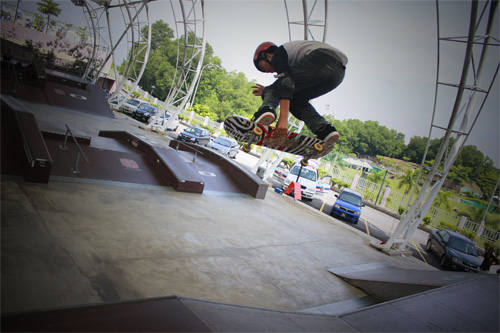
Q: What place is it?
A: It is a parking lot.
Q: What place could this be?
A: It is a parking lot.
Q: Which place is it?
A: It is a parking lot.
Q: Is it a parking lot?
A: Yes, it is a parking lot.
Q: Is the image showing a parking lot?
A: Yes, it is showing a parking lot.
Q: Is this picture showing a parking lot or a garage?
A: It is showing a parking lot.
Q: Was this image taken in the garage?
A: No, the picture was taken in the parking lot.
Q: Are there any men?
A: No, there are no men.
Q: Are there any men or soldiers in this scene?
A: No, there are no men or soldiers.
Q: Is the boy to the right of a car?
A: Yes, the boy is to the right of a car.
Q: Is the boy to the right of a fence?
A: No, the boy is to the right of a car.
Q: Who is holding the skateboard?
A: The boy is holding the skateboard.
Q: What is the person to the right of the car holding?
A: The boy is holding the skateboard.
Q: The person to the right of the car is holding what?
A: The boy is holding the skateboard.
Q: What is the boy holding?
A: The boy is holding the skateboard.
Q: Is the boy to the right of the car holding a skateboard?
A: Yes, the boy is holding a skateboard.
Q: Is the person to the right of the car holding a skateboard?
A: Yes, the boy is holding a skateboard.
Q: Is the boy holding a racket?
A: No, the boy is holding a skateboard.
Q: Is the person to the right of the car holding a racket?
A: No, the boy is holding a skateboard.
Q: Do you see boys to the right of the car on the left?
A: Yes, there is a boy to the right of the car.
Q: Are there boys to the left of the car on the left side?
A: No, the boy is to the right of the car.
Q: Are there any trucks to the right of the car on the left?
A: No, there is a boy to the right of the car.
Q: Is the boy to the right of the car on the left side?
A: Yes, the boy is to the right of the car.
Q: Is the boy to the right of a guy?
A: No, the boy is to the right of the car.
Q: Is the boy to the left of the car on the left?
A: No, the boy is to the right of the car.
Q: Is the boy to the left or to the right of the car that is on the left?
A: The boy is to the right of the car.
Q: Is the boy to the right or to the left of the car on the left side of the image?
A: The boy is to the right of the car.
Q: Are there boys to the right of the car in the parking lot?
A: Yes, there is a boy to the right of the car.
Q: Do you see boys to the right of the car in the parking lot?
A: Yes, there is a boy to the right of the car.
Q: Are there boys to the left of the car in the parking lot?
A: No, the boy is to the right of the car.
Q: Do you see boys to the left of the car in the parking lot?
A: No, the boy is to the right of the car.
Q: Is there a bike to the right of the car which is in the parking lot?
A: No, there is a boy to the right of the car.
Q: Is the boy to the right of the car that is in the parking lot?
A: Yes, the boy is to the right of the car.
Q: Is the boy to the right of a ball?
A: No, the boy is to the right of the car.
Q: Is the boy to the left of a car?
A: No, the boy is to the right of a car.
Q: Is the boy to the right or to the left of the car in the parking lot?
A: The boy is to the right of the car.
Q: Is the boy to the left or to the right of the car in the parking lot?
A: The boy is to the right of the car.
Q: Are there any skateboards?
A: Yes, there is a skateboard.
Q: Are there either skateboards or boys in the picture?
A: Yes, there is a skateboard.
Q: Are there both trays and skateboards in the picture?
A: No, there is a skateboard but no trays.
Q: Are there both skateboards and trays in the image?
A: No, there is a skateboard but no trays.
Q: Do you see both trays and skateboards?
A: No, there is a skateboard but no trays.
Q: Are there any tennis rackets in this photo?
A: No, there are no tennis rackets.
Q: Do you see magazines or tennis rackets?
A: No, there are no tennis rackets or magazines.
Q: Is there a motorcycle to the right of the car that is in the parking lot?
A: No, there is a skateboard to the right of the car.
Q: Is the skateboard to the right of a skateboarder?
A: No, the skateboard is to the right of the car.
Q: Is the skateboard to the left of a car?
A: No, the skateboard is to the right of a car.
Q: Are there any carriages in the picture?
A: No, there are no carriages.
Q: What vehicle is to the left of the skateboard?
A: The vehicle is a car.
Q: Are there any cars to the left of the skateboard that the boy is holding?
A: Yes, there is a car to the left of the skateboard.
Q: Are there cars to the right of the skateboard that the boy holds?
A: No, the car is to the left of the skateboard.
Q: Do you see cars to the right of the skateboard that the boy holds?
A: No, the car is to the left of the skateboard.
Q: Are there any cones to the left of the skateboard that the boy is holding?
A: No, there is a car to the left of the skateboard.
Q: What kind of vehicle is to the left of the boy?
A: The vehicle is a car.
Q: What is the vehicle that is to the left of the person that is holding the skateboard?
A: The vehicle is a car.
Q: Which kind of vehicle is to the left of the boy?
A: The vehicle is a car.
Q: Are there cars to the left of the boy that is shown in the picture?
A: Yes, there is a car to the left of the boy.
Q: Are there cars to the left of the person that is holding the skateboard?
A: Yes, there is a car to the left of the boy.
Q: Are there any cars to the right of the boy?
A: No, the car is to the left of the boy.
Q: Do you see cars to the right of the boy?
A: No, the car is to the left of the boy.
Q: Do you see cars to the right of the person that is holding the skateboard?
A: No, the car is to the left of the boy.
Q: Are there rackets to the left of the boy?
A: No, there is a car to the left of the boy.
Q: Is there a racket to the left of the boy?
A: No, there is a car to the left of the boy.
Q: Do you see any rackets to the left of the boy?
A: No, there is a car to the left of the boy.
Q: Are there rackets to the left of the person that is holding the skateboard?
A: No, there is a car to the left of the boy.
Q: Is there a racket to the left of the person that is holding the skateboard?
A: No, there is a car to the left of the boy.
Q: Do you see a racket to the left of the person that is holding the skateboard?
A: No, there is a car to the left of the boy.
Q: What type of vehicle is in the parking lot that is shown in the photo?
A: The vehicle is a car.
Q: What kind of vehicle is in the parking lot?
A: The vehicle is a car.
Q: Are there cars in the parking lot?
A: Yes, there is a car in the parking lot.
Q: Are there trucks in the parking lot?
A: No, there is a car in the parking lot.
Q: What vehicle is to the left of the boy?
A: The vehicle is a car.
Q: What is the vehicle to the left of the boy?
A: The vehicle is a car.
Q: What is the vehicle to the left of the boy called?
A: The vehicle is a car.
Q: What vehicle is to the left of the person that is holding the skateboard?
A: The vehicle is a car.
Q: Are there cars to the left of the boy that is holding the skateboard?
A: Yes, there is a car to the left of the boy.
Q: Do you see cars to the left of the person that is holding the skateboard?
A: Yes, there is a car to the left of the boy.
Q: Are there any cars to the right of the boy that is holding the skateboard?
A: No, the car is to the left of the boy.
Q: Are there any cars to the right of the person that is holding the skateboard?
A: No, the car is to the left of the boy.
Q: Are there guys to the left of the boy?
A: No, there is a car to the left of the boy.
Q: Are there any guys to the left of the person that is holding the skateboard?
A: No, there is a car to the left of the boy.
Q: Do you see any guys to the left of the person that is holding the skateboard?
A: No, there is a car to the left of the boy.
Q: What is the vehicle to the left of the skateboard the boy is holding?
A: The vehicle is a car.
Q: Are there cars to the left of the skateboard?
A: Yes, there is a car to the left of the skateboard.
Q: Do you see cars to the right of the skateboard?
A: No, the car is to the left of the skateboard.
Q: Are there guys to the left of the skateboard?
A: No, there is a car to the left of the skateboard.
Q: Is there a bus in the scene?
A: No, there are no buses.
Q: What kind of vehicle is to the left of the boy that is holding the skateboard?
A: The vehicle is a car.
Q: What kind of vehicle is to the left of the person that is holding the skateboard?
A: The vehicle is a car.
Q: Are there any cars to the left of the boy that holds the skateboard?
A: Yes, there is a car to the left of the boy.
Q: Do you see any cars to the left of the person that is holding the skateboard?
A: Yes, there is a car to the left of the boy.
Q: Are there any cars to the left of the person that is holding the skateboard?
A: Yes, there is a car to the left of the boy.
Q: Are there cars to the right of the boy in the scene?
A: No, the car is to the left of the boy.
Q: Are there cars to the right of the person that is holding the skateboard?
A: No, the car is to the left of the boy.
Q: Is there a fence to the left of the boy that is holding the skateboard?
A: No, there is a car to the left of the boy.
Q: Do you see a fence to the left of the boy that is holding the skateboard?
A: No, there is a car to the left of the boy.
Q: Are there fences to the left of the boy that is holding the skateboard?
A: No, there is a car to the left of the boy.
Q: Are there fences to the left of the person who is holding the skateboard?
A: No, there is a car to the left of the boy.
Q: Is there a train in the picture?
A: No, there are no trains.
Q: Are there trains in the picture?
A: No, there are no trains.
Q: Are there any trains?
A: No, there are no trains.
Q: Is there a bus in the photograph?
A: No, there are no buses.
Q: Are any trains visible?
A: No, there are no trains.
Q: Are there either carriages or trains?
A: No, there are no trains or carriages.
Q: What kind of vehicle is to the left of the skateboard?
A: The vehicle is a car.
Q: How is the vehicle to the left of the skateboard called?
A: The vehicle is a car.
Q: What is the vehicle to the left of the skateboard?
A: The vehicle is a car.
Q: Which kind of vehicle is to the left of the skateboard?
A: The vehicle is a car.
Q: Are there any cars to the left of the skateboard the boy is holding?
A: Yes, there is a car to the left of the skateboard.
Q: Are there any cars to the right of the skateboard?
A: No, the car is to the left of the skateboard.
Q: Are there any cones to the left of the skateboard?
A: No, there is a car to the left of the skateboard.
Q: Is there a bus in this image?
A: No, there are no buses.